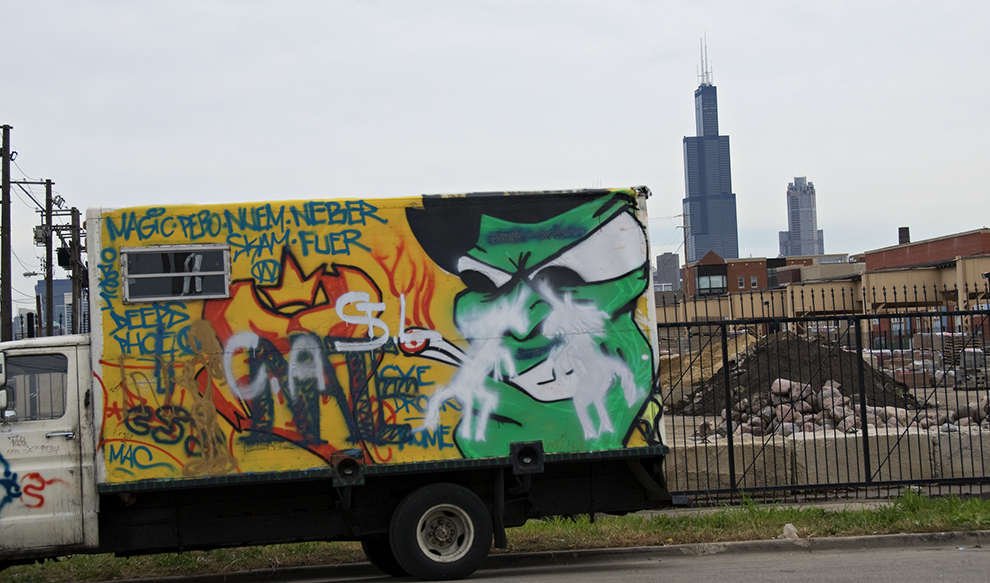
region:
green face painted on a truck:
[0, 187, 661, 568]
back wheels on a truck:
[358, 482, 495, 578]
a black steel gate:
[661, 287, 987, 503]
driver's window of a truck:
[0, 345, 72, 424]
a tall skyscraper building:
[675, 38, 749, 260]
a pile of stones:
[731, 376, 868, 441]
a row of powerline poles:
[4, 122, 94, 335]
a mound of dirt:
[679, 330, 915, 414]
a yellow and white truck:
[2, 184, 717, 572]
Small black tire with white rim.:
[405, 488, 487, 574]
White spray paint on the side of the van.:
[211, 273, 629, 427]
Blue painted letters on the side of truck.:
[112, 203, 406, 277]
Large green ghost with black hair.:
[383, 193, 688, 270]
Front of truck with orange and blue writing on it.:
[6, 313, 90, 561]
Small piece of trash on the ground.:
[772, 505, 798, 581]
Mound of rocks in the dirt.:
[697, 307, 882, 430]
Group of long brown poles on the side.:
[19, 167, 88, 329]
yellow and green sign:
[115, 218, 683, 512]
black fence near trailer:
[676, 328, 984, 520]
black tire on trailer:
[418, 475, 497, 557]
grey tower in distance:
[647, 68, 774, 254]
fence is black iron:
[709, 286, 875, 486]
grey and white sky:
[291, 57, 466, 195]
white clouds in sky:
[226, 8, 446, 177]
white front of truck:
[0, 331, 99, 562]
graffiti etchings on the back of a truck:
[49, 166, 659, 492]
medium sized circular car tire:
[349, 472, 500, 571]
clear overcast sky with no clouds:
[11, 9, 984, 249]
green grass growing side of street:
[514, 500, 979, 535]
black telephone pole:
[16, 161, 69, 325]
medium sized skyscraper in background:
[764, 171, 840, 251]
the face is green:
[492, 236, 574, 395]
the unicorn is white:
[533, 271, 632, 443]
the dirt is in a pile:
[757, 341, 830, 372]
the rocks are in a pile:
[764, 389, 823, 427]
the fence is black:
[900, 366, 976, 442]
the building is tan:
[802, 288, 847, 309]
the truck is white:
[7, 434, 64, 455]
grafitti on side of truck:
[85, 179, 680, 478]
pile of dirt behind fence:
[676, 315, 947, 452]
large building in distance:
[667, 32, 751, 271]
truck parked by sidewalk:
[4, 177, 682, 581]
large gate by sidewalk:
[649, 252, 988, 523]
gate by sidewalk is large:
[653, 276, 985, 510]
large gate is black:
[649, 266, 988, 521]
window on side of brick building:
[730, 271, 751, 295]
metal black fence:
[656, 275, 988, 515]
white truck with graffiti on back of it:
[0, 182, 678, 582]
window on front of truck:
[3, 347, 76, 431]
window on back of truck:
[113, 237, 241, 309]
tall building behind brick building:
[672, 28, 749, 261]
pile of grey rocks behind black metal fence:
[690, 373, 988, 446]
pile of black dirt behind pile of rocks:
[668, 322, 932, 428]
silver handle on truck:
[38, 425, 80, 449]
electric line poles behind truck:
[0, 118, 91, 344]